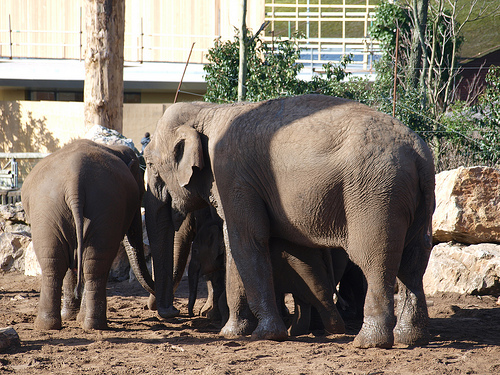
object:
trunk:
[142, 184, 176, 319]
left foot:
[323, 311, 347, 333]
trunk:
[124, 210, 154, 293]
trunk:
[182, 237, 204, 321]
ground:
[320, 343, 360, 375]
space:
[3, 211, 498, 374]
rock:
[433, 165, 498, 245]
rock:
[420, 240, 498, 317]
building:
[259, 1, 392, 87]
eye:
[146, 161, 154, 168]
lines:
[347, 150, 389, 206]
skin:
[228, 102, 403, 210]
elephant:
[136, 93, 441, 351]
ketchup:
[340, 150, 394, 211]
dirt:
[117, 332, 159, 369]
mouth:
[166, 188, 181, 232]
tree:
[207, 29, 301, 104]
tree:
[368, 0, 411, 109]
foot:
[394, 317, 432, 344]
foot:
[350, 314, 399, 349]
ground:
[2, 336, 81, 368]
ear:
[168, 123, 206, 188]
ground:
[391, 352, 492, 374]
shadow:
[415, 300, 499, 355]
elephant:
[146, 195, 352, 340]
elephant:
[18, 140, 152, 333]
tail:
[64, 199, 84, 302]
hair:
[70, 278, 83, 299]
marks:
[360, 317, 387, 333]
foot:
[252, 311, 291, 340]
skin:
[202, 104, 252, 139]